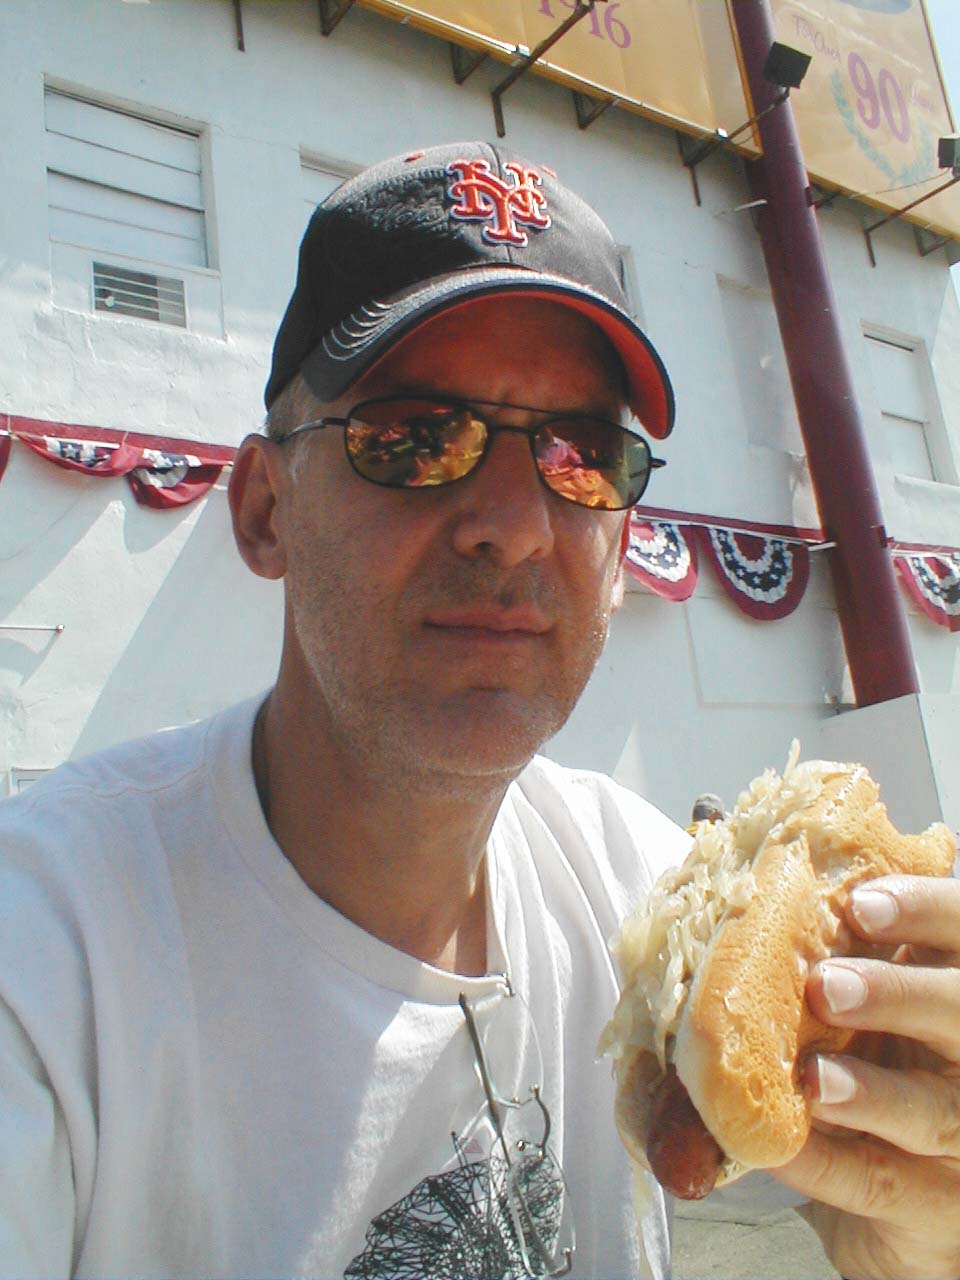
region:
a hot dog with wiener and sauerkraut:
[602, 744, 958, 1199]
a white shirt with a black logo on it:
[2, 686, 813, 1275]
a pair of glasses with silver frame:
[462, 973, 578, 1276]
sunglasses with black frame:
[261, 394, 664, 505]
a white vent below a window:
[49, 69, 228, 330]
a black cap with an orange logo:
[264, 135, 676, 440]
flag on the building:
[691, 536, 804, 642]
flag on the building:
[9, 420, 89, 469]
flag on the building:
[884, 528, 942, 610]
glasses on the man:
[536, 436, 605, 496]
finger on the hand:
[824, 1057, 904, 1135]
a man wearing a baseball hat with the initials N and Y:
[4, 139, 955, 1278]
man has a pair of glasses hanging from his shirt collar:
[0, 141, 955, 1279]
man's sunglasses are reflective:
[0, 139, 957, 1275]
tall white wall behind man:
[0, 0, 954, 1274]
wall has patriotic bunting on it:
[0, 0, 954, 868]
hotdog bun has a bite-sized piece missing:
[592, 736, 956, 1196]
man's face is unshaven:
[0, 139, 957, 1274]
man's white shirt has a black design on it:
[3, 141, 957, 1279]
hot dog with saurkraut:
[593, 738, 956, 1200]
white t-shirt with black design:
[0, 680, 687, 1276]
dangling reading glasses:
[449, 968, 582, 1275]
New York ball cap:
[261, 140, 677, 440]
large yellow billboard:
[341, 0, 958, 246]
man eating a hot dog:
[31, 73, 937, 1275]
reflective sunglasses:
[285, 394, 669, 513]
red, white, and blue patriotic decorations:
[0, 408, 954, 634]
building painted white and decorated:
[6, 6, 948, 824]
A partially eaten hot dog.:
[610, 745, 951, 1192]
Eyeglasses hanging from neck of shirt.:
[441, 956, 595, 1267]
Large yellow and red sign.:
[498, 2, 954, 242]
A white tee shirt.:
[0, 688, 744, 1277]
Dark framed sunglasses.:
[263, 386, 664, 530]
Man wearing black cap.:
[216, 120, 678, 934]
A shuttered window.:
[27, 70, 213, 251]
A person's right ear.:
[232, 423, 281, 587]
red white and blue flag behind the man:
[613, 517, 698, 597]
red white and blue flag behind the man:
[691, 523, 810, 621]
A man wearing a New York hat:
[1, 135, 955, 1277]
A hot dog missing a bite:
[600, 762, 957, 1204]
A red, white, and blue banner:
[0, 408, 958, 634]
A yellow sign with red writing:
[355, 0, 958, 234]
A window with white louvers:
[35, 71, 214, 269]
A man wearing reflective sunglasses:
[1, 141, 955, 1277]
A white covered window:
[853, 316, 957, 488]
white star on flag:
[58, 443, 85, 467]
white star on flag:
[643, 546, 660, 570]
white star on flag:
[661, 546, 677, 566]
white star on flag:
[658, 534, 688, 560]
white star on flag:
[661, 521, 677, 533]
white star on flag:
[713, 528, 736, 545]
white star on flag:
[734, 564, 747, 581]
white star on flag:
[749, 571, 765, 591]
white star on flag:
[770, 555, 790, 582]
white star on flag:
[664, 542, 681, 552]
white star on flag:
[716, 525, 732, 545]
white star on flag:
[720, 549, 736, 565]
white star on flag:
[728, 566, 752, 579]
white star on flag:
[750, 569, 766, 585]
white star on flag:
[763, 555, 790, 576]